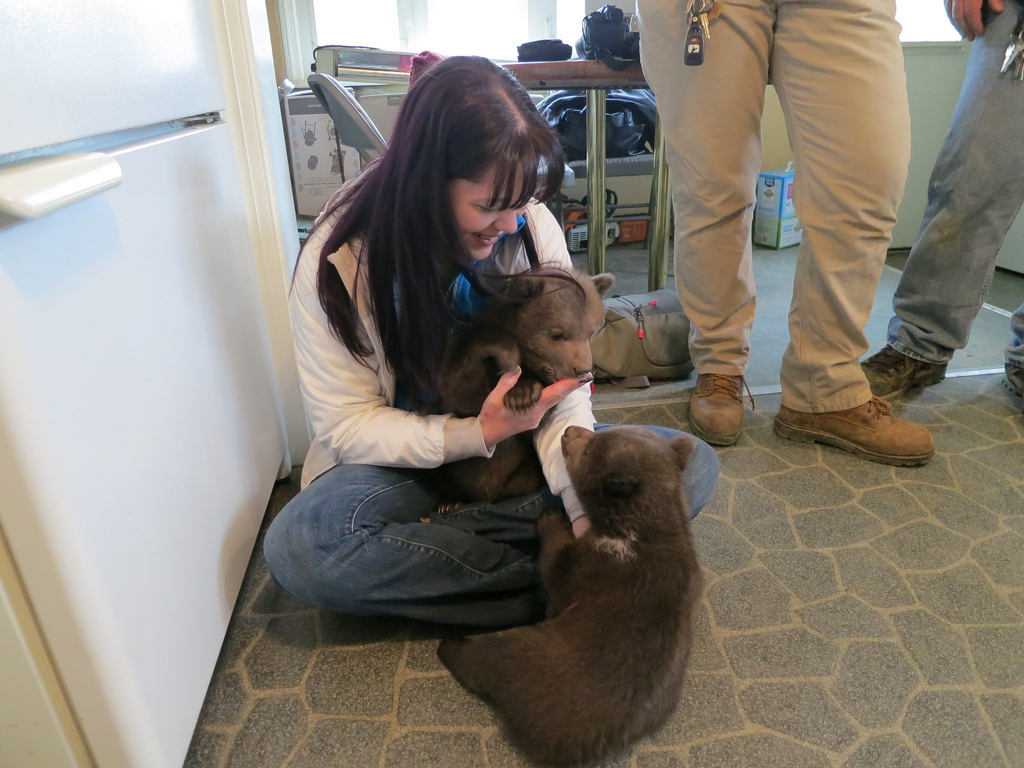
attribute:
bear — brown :
[471, 430, 721, 766]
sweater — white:
[264, 80, 690, 614]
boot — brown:
[667, 346, 760, 448]